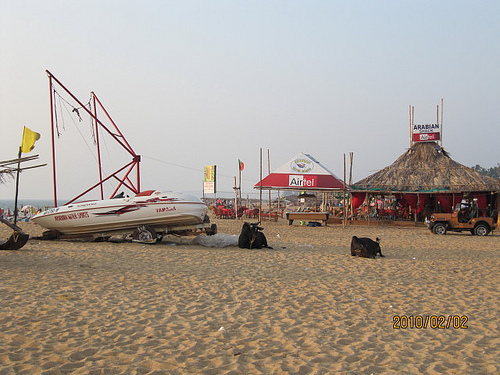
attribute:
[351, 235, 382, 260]
bag — black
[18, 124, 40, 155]
flag — yellow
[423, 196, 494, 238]
truck — brown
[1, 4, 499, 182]
sky — cloudy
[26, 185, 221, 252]
motor boat — white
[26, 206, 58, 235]
front — sharp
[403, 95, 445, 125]
poles — FOUR 